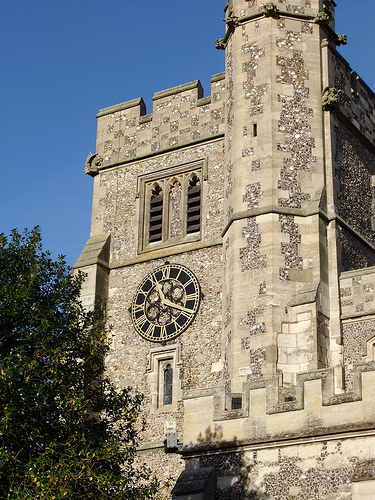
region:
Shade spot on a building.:
[181, 407, 268, 497]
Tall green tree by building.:
[5, 317, 173, 476]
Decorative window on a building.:
[147, 336, 207, 420]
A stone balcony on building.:
[192, 348, 368, 432]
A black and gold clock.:
[120, 288, 200, 335]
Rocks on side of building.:
[266, 456, 373, 495]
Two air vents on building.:
[121, 156, 207, 257]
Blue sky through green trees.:
[18, 288, 74, 394]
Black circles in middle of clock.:
[136, 288, 198, 326]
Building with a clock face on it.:
[66, 284, 316, 473]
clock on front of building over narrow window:
[105, 253, 226, 338]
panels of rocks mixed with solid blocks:
[235, 214, 265, 274]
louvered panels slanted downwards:
[140, 173, 215, 245]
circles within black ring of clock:
[108, 257, 208, 342]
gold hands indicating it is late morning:
[108, 252, 208, 344]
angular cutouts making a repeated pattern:
[210, 360, 370, 420]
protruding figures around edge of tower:
[199, 0, 351, 51]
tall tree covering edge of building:
[0, 222, 114, 492]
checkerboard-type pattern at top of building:
[102, 81, 216, 156]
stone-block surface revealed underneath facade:
[263, 301, 323, 392]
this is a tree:
[14, 264, 94, 441]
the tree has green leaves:
[22, 324, 92, 402]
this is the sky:
[16, 19, 95, 85]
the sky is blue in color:
[31, 32, 104, 69]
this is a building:
[118, 21, 353, 466]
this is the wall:
[244, 149, 275, 182]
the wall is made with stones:
[223, 250, 259, 295]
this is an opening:
[252, 123, 257, 136]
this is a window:
[157, 360, 171, 403]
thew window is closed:
[163, 367, 171, 401]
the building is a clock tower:
[88, 90, 257, 355]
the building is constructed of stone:
[15, 3, 369, 496]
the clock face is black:
[126, 259, 197, 341]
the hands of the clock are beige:
[129, 262, 200, 338]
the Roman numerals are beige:
[127, 261, 199, 344]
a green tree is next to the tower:
[0, 225, 166, 497]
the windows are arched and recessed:
[142, 168, 202, 243]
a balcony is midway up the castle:
[180, 352, 371, 440]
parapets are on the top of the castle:
[83, 2, 371, 184]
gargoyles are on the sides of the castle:
[319, 82, 344, 112]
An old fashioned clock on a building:
[125, 252, 212, 348]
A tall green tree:
[0, 225, 168, 499]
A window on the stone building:
[134, 155, 207, 250]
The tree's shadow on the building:
[164, 423, 262, 498]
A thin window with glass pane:
[145, 344, 192, 413]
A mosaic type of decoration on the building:
[276, 31, 311, 204]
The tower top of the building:
[214, 0, 338, 129]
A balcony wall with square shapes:
[173, 355, 374, 455]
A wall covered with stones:
[335, 134, 371, 234]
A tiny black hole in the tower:
[248, 121, 262, 139]